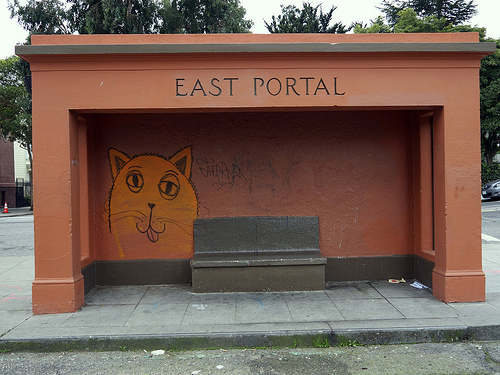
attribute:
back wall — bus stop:
[81, 107, 417, 283]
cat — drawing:
[106, 148, 195, 261]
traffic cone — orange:
[4, 199, 9, 213]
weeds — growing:
[309, 334, 362, 349]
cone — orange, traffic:
[1, 198, 11, 215]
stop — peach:
[12, 15, 498, 342]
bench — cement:
[180, 213, 329, 288]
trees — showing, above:
[2, 1, 498, 200]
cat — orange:
[102, 142, 215, 266]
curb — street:
[2, 323, 499, 351]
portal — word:
[250, 68, 354, 98]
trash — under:
[377, 271, 442, 303]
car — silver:
[483, 175, 499, 200]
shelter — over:
[14, 33, 485, 314]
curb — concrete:
[6, 330, 486, 350]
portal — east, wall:
[16, 28, 484, 310]